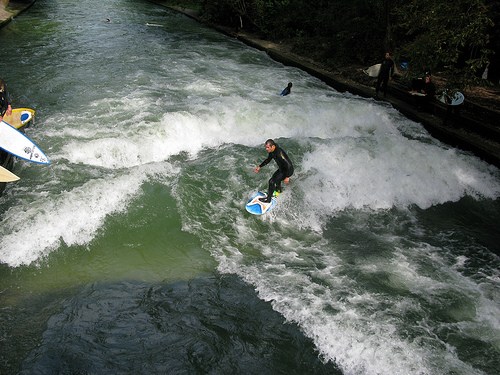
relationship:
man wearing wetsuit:
[252, 131, 294, 203] [267, 151, 290, 195]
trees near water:
[239, 0, 488, 78] [36, 60, 423, 298]